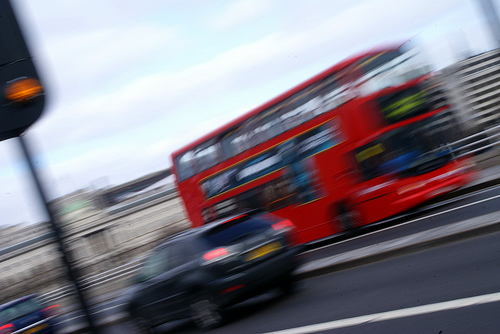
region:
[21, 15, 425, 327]
blurry image of bus and car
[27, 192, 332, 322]
blurry image of a car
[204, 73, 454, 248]
blurry image of a bus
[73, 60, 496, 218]
red double decker bus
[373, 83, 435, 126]
front electronic sign on bus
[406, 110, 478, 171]
front driver window on bus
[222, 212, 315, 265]
yellow license plate on car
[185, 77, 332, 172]
seats on top of bus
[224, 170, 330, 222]
window on bottom of bus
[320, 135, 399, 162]
sign on side of red bus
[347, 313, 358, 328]
the line is white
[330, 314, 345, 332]
the line is white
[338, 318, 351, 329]
the line is white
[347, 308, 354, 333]
the line is white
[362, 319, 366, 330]
the line is white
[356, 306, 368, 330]
the line is white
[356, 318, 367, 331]
the line is white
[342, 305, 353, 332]
the line is white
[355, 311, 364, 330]
the line is white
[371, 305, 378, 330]
the line is white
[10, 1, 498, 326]
photo is blurry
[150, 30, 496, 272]
a double decker bus is red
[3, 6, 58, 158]
a traffic light on the corner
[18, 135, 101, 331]
pole of traffic light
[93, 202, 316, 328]
car is black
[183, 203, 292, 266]
car has red lights on back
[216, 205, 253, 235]
signal light on car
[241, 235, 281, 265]
yellow plate on a car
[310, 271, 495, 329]
white line on a road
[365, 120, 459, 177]
windshield of red bus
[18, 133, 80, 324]
Black metal traffic signal post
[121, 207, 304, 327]
Dark green cross-over with red brake lights on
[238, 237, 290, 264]
Rear license plate is dark yellow and rectangular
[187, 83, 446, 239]
Red double-decker bus being driven down the street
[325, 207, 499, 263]
Elevated two-tone concrete median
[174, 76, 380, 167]
Passenger windows on top level of bus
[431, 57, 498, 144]
Multi-level concrete parking garage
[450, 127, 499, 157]
Gray steel protective fencing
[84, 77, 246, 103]
Big white cloud in the sky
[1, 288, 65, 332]
Bright blue SUV in front of other vehicles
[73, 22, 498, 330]
a blurry picture of a two decker bus and a car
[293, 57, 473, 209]
a blurry picture of a two decker bus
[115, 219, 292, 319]
a blurry picture of a black car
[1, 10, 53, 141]
a part of a traffic light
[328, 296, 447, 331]
a solid white paint in the middle of the road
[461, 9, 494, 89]
a blurry picture of a building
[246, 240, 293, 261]
a blurry picture of a plate number of a car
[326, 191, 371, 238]
a blurry picture of the front wheel of a bus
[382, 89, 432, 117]
a blurry sign of a bus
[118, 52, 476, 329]
two vehicles in opposite direction